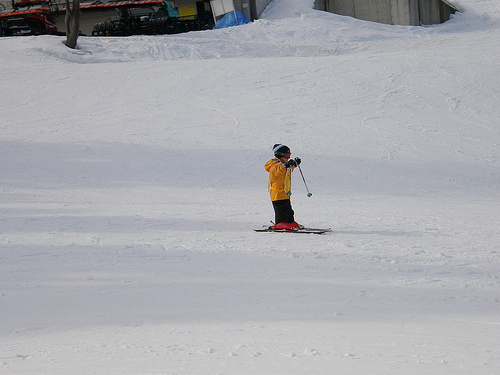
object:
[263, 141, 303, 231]
boy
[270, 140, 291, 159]
hat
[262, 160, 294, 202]
coat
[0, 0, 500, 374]
snow